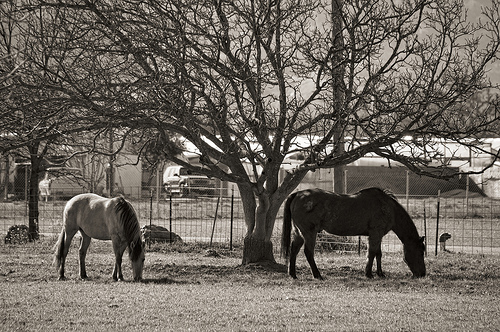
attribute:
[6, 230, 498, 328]
field — green, grassy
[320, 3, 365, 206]
pole — large, wooden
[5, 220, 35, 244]
bush — small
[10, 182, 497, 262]
fence — long, metal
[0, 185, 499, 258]
wire fence — metal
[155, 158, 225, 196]
suv — truck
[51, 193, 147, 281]
horse — grey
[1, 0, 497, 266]
tree — large, leafless